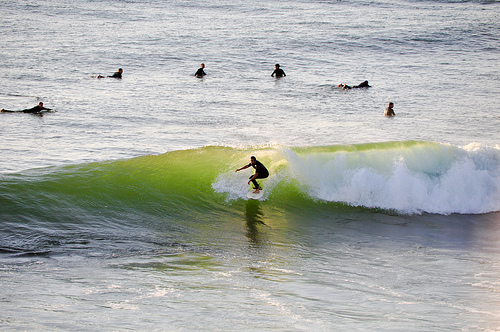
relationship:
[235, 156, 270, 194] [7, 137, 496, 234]
guy surfing a wave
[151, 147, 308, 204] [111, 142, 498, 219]
reflection on wave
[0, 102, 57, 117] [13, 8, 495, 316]
person in ocean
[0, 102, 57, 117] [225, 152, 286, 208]
person watching surfer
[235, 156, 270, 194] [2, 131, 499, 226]
guy riding wave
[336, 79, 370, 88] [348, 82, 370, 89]
person wearing wetsuit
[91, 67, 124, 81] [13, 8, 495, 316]
surfer in ocean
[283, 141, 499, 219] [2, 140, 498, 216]
caps on wave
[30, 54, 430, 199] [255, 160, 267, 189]
seven people wearing suit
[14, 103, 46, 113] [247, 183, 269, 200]
person lying on surfboard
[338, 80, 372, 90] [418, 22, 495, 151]
person paddling in water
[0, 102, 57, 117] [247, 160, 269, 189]
person are wearing suit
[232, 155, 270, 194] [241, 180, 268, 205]
guy on surfboard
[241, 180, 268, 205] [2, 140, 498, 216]
surfboard on wave